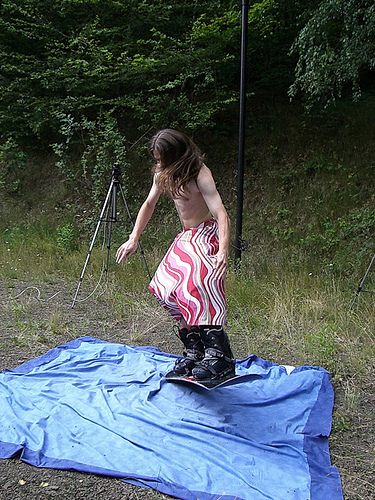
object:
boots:
[192, 326, 236, 379]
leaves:
[150, 28, 158, 33]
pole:
[234, 1, 247, 269]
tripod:
[70, 178, 153, 309]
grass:
[12, 329, 24, 347]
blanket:
[0, 334, 346, 499]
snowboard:
[160, 372, 263, 393]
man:
[115, 127, 236, 389]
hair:
[149, 129, 207, 199]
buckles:
[201, 351, 217, 359]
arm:
[194, 166, 232, 249]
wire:
[9, 222, 106, 303]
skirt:
[148, 218, 228, 326]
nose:
[161, 375, 210, 391]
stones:
[7, 475, 50, 487]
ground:
[0, 248, 374, 499]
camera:
[112, 159, 122, 184]